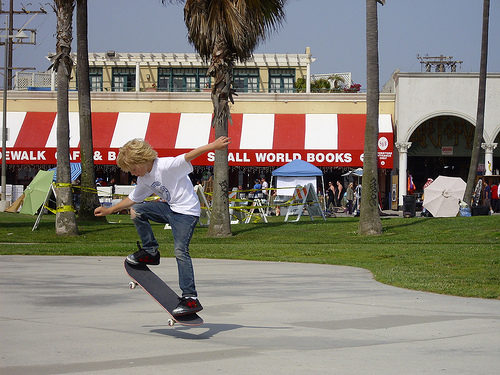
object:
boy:
[94, 135, 233, 317]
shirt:
[126, 152, 202, 218]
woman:
[326, 181, 335, 212]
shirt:
[328, 187, 334, 196]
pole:
[7, 0, 14, 91]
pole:
[357, 0, 382, 237]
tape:
[228, 186, 302, 193]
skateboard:
[123, 257, 204, 327]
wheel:
[129, 281, 137, 289]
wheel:
[167, 318, 174, 326]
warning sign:
[284, 183, 327, 223]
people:
[336, 180, 347, 212]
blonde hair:
[115, 137, 158, 173]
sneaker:
[171, 297, 203, 318]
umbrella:
[47, 162, 82, 181]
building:
[43, 46, 317, 94]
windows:
[268, 68, 296, 94]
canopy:
[1, 111, 394, 169]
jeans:
[130, 200, 200, 297]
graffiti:
[368, 176, 377, 207]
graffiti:
[219, 180, 229, 199]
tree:
[357, 0, 388, 237]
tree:
[158, 0, 288, 238]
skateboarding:
[93, 135, 232, 328]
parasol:
[19, 170, 54, 216]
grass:
[0, 214, 500, 300]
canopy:
[271, 158, 324, 177]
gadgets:
[0, 67, 36, 79]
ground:
[0, 210, 500, 375]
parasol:
[422, 175, 468, 218]